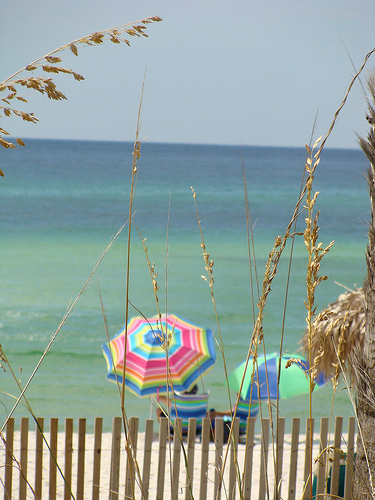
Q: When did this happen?
A: During the day time.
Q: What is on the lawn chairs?
A: Umbrellas.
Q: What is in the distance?
A: Body of water.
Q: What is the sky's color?
A: Blue.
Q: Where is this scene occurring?
A: On beach at the ocean.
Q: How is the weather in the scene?
A: Warm and sunny.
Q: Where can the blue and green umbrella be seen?
A: On beach, behind fence on right.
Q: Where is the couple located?
A: In beach chairs on beach under umbrellas.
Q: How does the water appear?
A: Calm and clear.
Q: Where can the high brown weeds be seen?
A: In forefront behind the fence.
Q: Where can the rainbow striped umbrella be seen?
A: Behind the fence middle slightly left.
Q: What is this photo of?
A: A beach.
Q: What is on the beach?
A: Sand.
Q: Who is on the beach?
A: Two people.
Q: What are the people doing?
A: Sitting.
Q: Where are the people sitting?
A: In chairs.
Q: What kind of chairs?
A: Beach chairs.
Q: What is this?
A: Water.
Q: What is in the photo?
A: Umbrella.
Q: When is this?
A: Daytime.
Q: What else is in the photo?
A: Sand.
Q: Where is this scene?
A: At the beach.